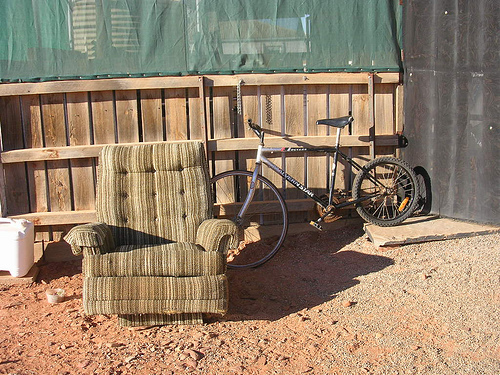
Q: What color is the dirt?
A: Red.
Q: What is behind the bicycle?
A: Wall.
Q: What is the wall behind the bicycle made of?
A: Wood.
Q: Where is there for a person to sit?
A: Chair.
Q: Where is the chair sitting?
A: In the dirt.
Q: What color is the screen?
A: Green.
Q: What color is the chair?
A: Brown and tan.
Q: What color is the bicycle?
A: Black and gray.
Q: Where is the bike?
A: Behind the chair.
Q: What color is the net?
A: Green.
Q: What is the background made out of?
A: Wood.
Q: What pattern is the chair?
A: Striped.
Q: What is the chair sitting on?
A: Sand.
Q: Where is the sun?
A: Shining on the chair.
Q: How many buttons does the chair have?
A: 9.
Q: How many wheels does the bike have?
A: 2.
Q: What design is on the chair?
A: Stripes.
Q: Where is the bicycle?
A: Behind the chair.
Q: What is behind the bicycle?
A: A fence.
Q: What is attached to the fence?
A: A tarp.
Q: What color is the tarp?
A: Green.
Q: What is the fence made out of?
A: Wood.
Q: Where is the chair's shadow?
A: On the dirt.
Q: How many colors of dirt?
A: Two.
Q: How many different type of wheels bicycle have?
A: Two.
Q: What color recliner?
A: Yellow.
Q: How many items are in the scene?
A: 3.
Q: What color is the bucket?
A: White.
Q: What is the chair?
A: A recliner.